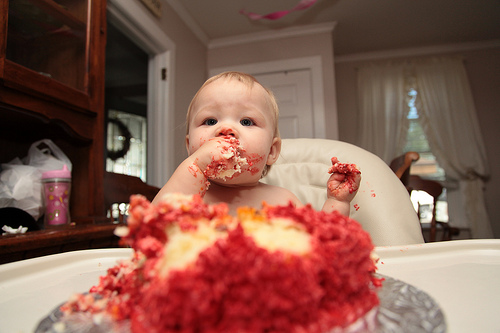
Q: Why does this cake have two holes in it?
A: The baby started eating the cake.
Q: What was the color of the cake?
A: Pink.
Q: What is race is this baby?
A: White.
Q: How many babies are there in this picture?
A: One.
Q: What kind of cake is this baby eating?
A: A strawberry cake.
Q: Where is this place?
A: A dining room.